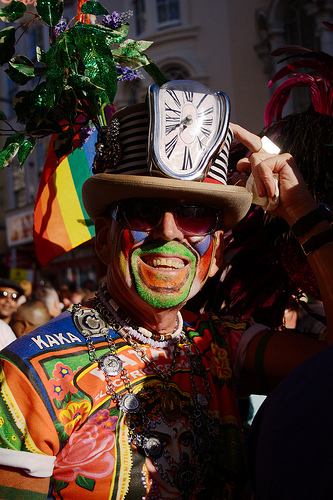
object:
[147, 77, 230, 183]
clock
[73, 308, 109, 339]
bottlecap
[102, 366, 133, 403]
chain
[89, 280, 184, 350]
necklace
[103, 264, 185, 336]
neck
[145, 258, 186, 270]
teeth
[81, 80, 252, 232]
hat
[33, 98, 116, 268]
flag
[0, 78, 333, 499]
man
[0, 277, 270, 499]
shirt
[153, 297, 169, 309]
beard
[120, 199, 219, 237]
sunglasses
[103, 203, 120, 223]
hair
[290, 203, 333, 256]
bracelet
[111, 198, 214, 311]
face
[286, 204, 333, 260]
watch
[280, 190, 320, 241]
wrist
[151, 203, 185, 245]
nose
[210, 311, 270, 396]
sleeve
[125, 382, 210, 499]
woman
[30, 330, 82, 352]
letters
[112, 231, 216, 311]
makeup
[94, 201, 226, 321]
head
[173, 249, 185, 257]
paint